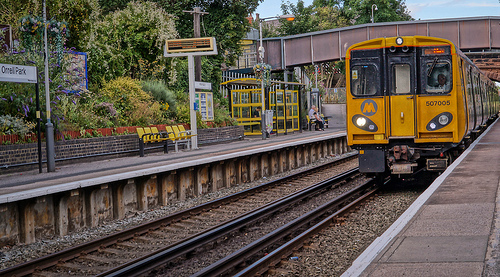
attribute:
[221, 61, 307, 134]
area — yellow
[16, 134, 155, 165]
wall — brick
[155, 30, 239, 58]
sign — yellow, bordered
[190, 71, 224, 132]
sign — white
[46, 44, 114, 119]
sign — white, blue, bordered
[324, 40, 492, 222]
train — yellow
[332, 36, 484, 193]
train — yellow, long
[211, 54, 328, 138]
sheter — yellow, black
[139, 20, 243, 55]
sign — black, yellow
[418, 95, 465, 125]
numbers — black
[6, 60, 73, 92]
sign — white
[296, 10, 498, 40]
bridge — above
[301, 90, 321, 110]
shirt — gray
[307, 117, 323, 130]
pants — black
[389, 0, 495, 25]
sky — blue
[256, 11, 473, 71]
walkway — over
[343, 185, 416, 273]
line — white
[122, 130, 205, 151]
seats — facing, yellow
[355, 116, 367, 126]
light — glowing, round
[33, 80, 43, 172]
pole — black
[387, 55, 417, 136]
door — yellow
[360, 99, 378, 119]
decal — gray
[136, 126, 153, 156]
chair — yellow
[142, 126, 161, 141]
chair — yellow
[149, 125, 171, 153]
chair — yellow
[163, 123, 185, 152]
chair — yellow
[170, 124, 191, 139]
chair — yellow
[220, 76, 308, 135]
building — yellow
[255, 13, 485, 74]
walking bridge — gray, stone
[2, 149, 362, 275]
train track — metal, wooden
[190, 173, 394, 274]
train track — metal, wooden